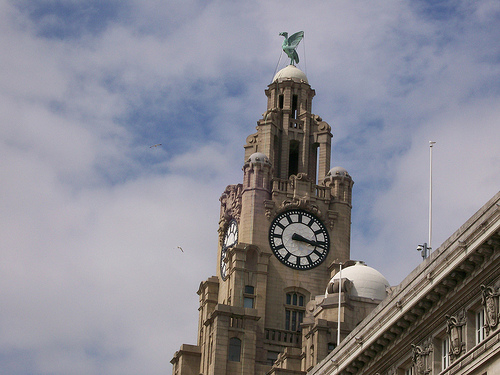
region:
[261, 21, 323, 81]
stone statue on top of the clock tower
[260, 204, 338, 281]
clock with roman numerals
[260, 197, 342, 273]
clock reading 3:17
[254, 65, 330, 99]
dome on a clock tower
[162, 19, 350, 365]
clock tower next to a stone building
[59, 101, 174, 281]
fluffy clouds in a blue sky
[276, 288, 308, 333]
arched windows in a clock tower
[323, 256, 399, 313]
white dome on a building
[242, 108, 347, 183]
pillars on top of the clock tower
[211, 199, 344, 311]
two sides of a clock tower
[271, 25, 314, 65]
Antique green statue at the top of tower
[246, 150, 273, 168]
Small, gray decorative domes on tower above clock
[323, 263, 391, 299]
White and taupe dome design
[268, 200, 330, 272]
Large circular clock with black numerals and black hands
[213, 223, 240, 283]
Large front of building clock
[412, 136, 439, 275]
White lightning rod on roof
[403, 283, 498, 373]
Ornate decoration near roof building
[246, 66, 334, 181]
Top of clock tower and beneath green statue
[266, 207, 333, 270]
White abalone circular clock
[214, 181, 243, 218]
Ornate designs above front facing clock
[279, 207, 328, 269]
black and white clock face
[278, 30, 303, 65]
green statue of winged animal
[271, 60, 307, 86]
cream colored dome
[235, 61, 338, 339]
large brick clock tower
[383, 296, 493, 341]
set of windows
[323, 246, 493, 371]
white gutter along a brick building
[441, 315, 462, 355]
decorative art between windows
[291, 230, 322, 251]
black hands of a clock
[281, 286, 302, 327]
clock tower's windows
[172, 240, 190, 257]
small bird flying past the clock tower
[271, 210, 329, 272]
a clock on the side of a building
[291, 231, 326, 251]
the clock hands are black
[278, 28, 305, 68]
a statue of a bird on the roof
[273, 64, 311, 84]
a white dome roof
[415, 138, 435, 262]
a security light on the roof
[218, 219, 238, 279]
another clock on the side of the building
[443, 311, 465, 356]
statues on the side of the windows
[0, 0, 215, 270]
blue sky with white clouds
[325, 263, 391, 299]
a white dome roof on a lower floor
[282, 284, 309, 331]
an arched window below the clock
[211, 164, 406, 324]
Clock on the building.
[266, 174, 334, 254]
Hands on the clock.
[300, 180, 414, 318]
Dome on the building.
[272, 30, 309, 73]
Statue on the building.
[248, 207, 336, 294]
White face of the clock.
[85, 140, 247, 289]
Clouds in the sky.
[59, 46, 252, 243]
Blue sky with clouds.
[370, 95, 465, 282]
Pole on the building.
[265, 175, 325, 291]
Black hands on the clock.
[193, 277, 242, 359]
Columns on the building.